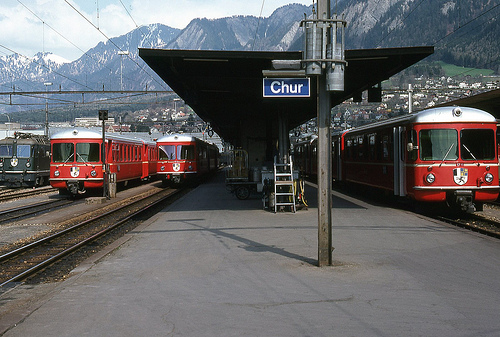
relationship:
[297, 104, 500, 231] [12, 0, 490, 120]
train near mountains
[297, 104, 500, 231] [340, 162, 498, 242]
train on tracks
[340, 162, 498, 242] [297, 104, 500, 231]
tracks under train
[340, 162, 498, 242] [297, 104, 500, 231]
tracks below train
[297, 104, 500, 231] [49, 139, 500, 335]
train near pavement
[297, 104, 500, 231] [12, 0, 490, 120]
train close to mountains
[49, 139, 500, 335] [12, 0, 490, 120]
pavement close to mountains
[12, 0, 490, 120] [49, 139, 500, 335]
mountains above pavement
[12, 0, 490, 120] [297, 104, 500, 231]
mountains above train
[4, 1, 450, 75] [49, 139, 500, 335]
sky above pavement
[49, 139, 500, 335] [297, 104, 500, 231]
pavement close to train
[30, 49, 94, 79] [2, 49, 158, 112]
mountain in mountain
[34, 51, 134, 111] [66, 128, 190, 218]
power lines are passing above train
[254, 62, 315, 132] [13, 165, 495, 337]
sign at train station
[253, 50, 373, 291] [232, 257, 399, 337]
pole in foreground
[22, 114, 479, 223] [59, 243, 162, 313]
three trains are bright red in color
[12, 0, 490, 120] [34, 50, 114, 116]
mountains are in background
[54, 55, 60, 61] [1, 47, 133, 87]
snow on top of mountain